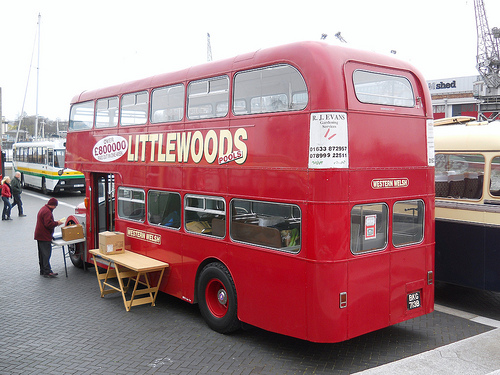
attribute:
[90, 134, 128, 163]
sign — oblong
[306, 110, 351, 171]
sign — rectangular, white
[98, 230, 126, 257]
box — cardboard, brown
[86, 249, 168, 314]
table — wooden, small, brown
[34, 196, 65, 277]
man — standing, setting up table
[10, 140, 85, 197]
bus — white, yellow, green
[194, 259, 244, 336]
tire — black, in rear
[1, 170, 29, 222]
people — walking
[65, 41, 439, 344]
bus — doubledecker, red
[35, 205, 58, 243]
coat — red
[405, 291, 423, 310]
license plate — black, white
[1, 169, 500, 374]
parking lot — patterned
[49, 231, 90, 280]
table — small, white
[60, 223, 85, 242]
box — brown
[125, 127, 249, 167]
advertisment — for pools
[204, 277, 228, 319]
tire rim — red